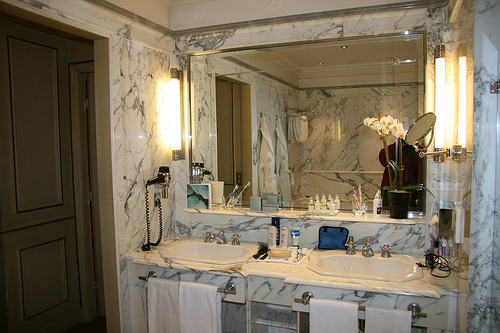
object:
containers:
[252, 217, 316, 265]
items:
[415, 198, 466, 278]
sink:
[307, 249, 424, 283]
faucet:
[203, 227, 241, 246]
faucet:
[345, 236, 393, 258]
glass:
[351, 199, 366, 219]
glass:
[221, 193, 243, 210]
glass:
[361, 188, 362, 195]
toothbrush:
[225, 181, 251, 207]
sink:
[159, 241, 253, 265]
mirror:
[187, 33, 427, 220]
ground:
[412, 168, 454, 210]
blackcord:
[416, 250, 452, 278]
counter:
[129, 237, 475, 332]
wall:
[115, 5, 495, 252]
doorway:
[0, 3, 113, 332]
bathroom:
[0, 0, 494, 330]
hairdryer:
[141, 166, 172, 251]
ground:
[377, 102, 449, 164]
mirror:
[405, 112, 437, 144]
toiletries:
[252, 217, 308, 263]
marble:
[267, 257, 377, 307]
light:
[168, 67, 182, 161]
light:
[433, 43, 447, 163]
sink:
[125, 236, 470, 332]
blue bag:
[318, 226, 349, 250]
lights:
[171, 42, 465, 160]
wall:
[111, 35, 181, 256]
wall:
[468, 77, 483, 307]